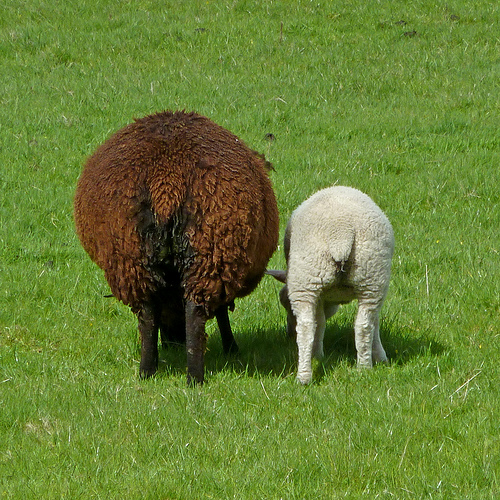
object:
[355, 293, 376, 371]
legs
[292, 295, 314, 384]
legs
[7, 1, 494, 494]
grass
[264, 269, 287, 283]
ear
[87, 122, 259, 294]
wool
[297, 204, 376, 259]
wool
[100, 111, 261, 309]
butt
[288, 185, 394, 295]
butt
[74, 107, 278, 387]
animal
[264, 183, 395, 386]
animal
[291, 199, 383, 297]
plate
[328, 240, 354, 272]
tail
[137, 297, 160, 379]
leg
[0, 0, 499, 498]
field